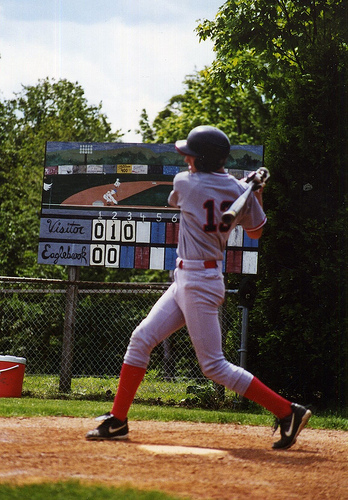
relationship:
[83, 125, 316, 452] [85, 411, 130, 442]
boy wearing shoe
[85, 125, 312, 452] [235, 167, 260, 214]
boy swinging bat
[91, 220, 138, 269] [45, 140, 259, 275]
numbers on scoreboard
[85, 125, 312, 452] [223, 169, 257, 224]
boy swinging baseball bat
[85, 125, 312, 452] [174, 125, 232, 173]
boy wearing helmet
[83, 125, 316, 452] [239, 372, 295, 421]
boy wearing sock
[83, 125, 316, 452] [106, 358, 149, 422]
boy wearing sock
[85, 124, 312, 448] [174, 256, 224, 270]
man wearing belt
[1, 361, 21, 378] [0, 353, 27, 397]
handle on cooler